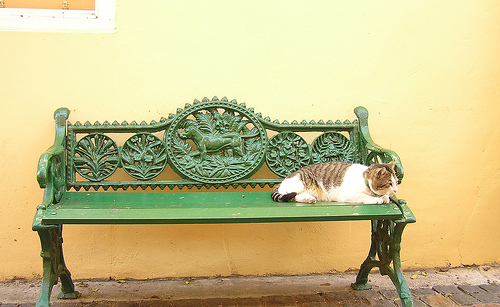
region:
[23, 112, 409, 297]
a green bench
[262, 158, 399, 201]
a white and brown cat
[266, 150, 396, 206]
a cat laying down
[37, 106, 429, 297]
a cat laying on a green bench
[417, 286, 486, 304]
bricks on the ground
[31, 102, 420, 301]
a green steel bench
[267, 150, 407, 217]
a cat looking at the ground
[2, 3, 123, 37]
a window on the wall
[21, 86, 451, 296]
a green bench ade of metal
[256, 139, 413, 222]
a brown and white cat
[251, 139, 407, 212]
this cat is lying down on the bench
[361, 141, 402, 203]
the cat's head is brown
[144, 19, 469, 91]
the wall is tan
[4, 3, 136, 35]
a window seal on the wall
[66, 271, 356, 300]
concrete ground beneath the bench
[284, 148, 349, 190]
the cat has a brown spot with black stripes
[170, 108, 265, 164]
an emblem of a dog on a bench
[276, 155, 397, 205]
A cat lying on a bench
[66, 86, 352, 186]
Backrest of a decorative bench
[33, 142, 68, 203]
The armrest of a green bench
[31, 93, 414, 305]
A green bench in front of a beige wall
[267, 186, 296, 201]
The striped tail of a cat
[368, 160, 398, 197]
The head of a cat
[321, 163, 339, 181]
Gray fur on a cat's side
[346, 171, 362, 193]
White fur on a cat's torso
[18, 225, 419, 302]
Legs on a green bench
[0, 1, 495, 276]
bottom white frame of window on yellow wall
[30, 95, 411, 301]
metal bench next to wall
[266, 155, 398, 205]
cat lying on one end of bench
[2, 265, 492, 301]
gray border next to brick surface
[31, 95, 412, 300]
green bench with ornate back and curved legs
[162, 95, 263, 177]
hunting dog surrounded by leaves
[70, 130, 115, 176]
flowers and stems within a circle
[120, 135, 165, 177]
flowers above horizontal leaves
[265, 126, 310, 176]
flowers within circle of leaves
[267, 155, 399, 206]
white cat with dark striped patches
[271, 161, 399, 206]
white and brown striped cat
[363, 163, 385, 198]
blue collar around cat's neck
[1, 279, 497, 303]
ground is made of gray brick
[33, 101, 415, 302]
green metal bench against a wall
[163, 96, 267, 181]
a dog design on the back of the bench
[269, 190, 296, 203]
brown striped cat tail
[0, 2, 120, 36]
corner of a window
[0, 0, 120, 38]
window has a white frame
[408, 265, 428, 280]
two yellow leaves laying on the sidewalk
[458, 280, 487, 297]
a brick in a sidewalk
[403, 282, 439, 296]
a brick in a sidewalk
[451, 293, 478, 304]
a brick in a sidewalk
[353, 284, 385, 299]
a brick in a sidewalk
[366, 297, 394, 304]
a brick in a sidewalk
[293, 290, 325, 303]
a brick in a sidewalk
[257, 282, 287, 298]
a brick in a sidewalk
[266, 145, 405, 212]
cat on a bench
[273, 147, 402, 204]
cat on a green bench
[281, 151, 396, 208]
cat on an old bench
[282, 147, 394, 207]
cat on an old green bench